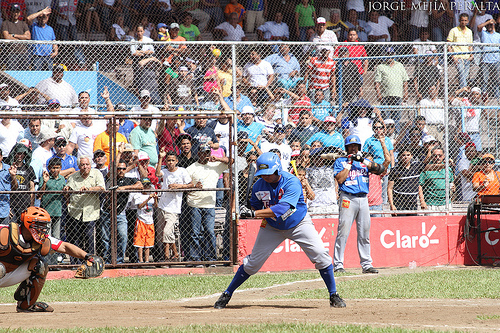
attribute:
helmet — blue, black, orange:
[256, 150, 282, 182]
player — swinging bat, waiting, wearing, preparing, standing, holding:
[220, 152, 346, 316]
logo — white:
[251, 189, 276, 205]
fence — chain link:
[1, 34, 498, 267]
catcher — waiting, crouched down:
[3, 208, 103, 320]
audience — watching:
[4, 6, 487, 258]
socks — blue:
[220, 268, 342, 295]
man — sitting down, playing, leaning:
[124, 155, 163, 267]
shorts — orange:
[136, 218, 156, 247]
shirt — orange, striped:
[477, 170, 499, 198]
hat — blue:
[158, 22, 169, 27]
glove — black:
[77, 254, 107, 276]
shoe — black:
[217, 293, 346, 315]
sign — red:
[343, 200, 350, 208]